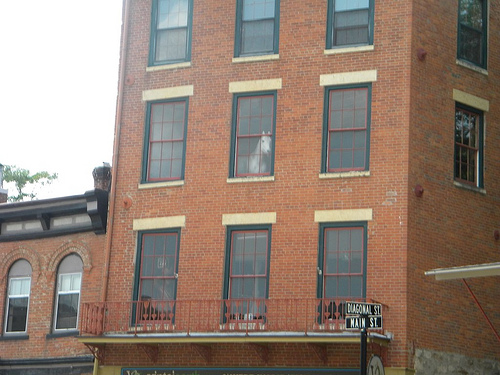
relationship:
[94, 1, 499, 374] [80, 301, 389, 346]
building has balcony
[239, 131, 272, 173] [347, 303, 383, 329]
horse in words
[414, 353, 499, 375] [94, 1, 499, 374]
poster beside building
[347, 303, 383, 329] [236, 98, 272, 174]
words has glass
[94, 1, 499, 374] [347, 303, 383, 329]
building has words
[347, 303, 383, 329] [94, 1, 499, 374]
signs near building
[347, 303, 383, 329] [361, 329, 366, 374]
signs have pole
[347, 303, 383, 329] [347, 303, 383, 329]
words on signs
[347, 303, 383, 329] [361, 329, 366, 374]
signs on pole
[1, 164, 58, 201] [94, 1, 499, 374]
trees near building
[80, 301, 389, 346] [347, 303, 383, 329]
balcony near words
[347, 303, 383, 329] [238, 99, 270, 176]
words has bars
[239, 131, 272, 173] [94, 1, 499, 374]
horse in building